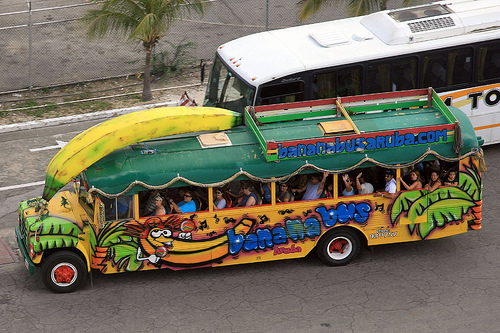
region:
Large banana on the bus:
[14, 82, 369, 212]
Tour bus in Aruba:
[64, 103, 377, 253]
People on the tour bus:
[129, 157, 496, 226]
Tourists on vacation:
[157, 175, 329, 238]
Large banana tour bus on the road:
[50, 97, 365, 265]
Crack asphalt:
[203, 273, 305, 329]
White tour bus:
[218, 30, 430, 108]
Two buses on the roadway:
[151, 50, 483, 255]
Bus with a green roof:
[98, 120, 355, 200]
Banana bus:
[220, 185, 379, 270]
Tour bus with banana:
[26, 109, 492, 275]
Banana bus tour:
[185, 184, 426, 277]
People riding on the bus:
[3, 143, 489, 248]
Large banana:
[34, 95, 371, 257]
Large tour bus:
[15, 62, 458, 307]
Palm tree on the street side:
[126, 2, 176, 95]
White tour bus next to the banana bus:
[178, 25, 482, 107]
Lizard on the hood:
[20, 153, 117, 238]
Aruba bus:
[271, 112, 495, 236]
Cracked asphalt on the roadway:
[231, 292, 330, 327]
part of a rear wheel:
[328, 232, 359, 263]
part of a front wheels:
[51, 261, 86, 283]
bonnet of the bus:
[36, 203, 62, 236]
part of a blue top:
[186, 205, 196, 215]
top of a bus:
[281, 125, 340, 149]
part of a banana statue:
[168, 123, 201, 146]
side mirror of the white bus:
[187, 53, 204, 84]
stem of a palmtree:
[143, 75, 160, 100]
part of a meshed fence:
[67, 30, 97, 63]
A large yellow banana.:
[34, 90, 241, 210]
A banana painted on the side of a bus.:
[120, 213, 257, 268]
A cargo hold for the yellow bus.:
[243, 83, 459, 168]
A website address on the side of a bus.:
[261, 119, 488, 172]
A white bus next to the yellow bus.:
[181, 1, 498, 175]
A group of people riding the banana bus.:
[137, 153, 461, 224]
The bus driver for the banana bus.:
[88, 181, 138, 229]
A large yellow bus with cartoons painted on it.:
[14, 84, 488, 303]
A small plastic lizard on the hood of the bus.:
[51, 190, 75, 217]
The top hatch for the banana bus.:
[190, 126, 233, 156]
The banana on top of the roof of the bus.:
[25, 98, 250, 200]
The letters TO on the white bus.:
[470, 88, 498, 110]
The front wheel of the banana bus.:
[37, 250, 90, 293]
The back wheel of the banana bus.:
[320, 225, 355, 263]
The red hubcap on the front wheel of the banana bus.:
[52, 265, 75, 282]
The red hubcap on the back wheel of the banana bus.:
[327, 240, 344, 255]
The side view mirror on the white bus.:
[190, 48, 217, 85]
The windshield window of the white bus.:
[211, 58, 249, 108]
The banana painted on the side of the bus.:
[127, 222, 257, 272]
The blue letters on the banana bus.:
[215, 198, 374, 248]